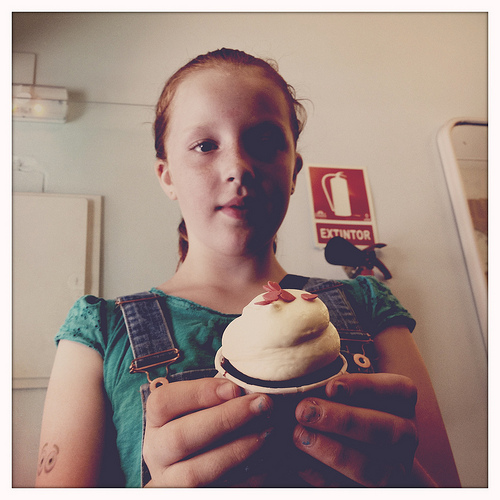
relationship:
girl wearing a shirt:
[1, 47, 463, 479] [89, 269, 456, 387]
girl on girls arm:
[1, 47, 463, 479] [33, 337, 103, 487]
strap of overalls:
[113, 291, 185, 378] [111, 272, 392, 491]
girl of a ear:
[1, 47, 463, 479] [146, 146, 181, 198]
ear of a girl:
[289, 148, 306, 195] [1, 47, 463, 479]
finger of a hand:
[143, 377, 238, 423] [143, 375, 272, 486]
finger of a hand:
[135, 391, 269, 456] [143, 375, 272, 486]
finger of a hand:
[151, 425, 277, 483] [143, 375, 272, 486]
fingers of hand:
[282, 373, 425, 483] [292, 346, 452, 483]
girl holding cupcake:
[1, 47, 463, 479] [212, 275, 351, 428]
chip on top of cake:
[300, 289, 317, 300] [219, 278, 341, 389]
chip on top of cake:
[278, 287, 296, 303] [219, 278, 341, 389]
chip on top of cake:
[256, 292, 277, 306] [219, 278, 341, 389]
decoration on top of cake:
[262, 291, 279, 302] [219, 278, 341, 389]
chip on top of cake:
[262, 279, 281, 291] [219, 278, 341, 389]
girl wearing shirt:
[1, 47, 463, 479] [55, 273, 450, 491]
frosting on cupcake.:
[215, 280, 342, 375] [159, 273, 397, 393]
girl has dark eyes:
[95, 38, 426, 458] [193, 137, 320, 165]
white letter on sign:
[361, 223, 375, 243] [300, 153, 381, 254]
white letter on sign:
[341, 225, 355, 245] [300, 153, 381, 254]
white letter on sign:
[314, 223, 331, 244] [300, 153, 381, 254]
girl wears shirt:
[1, 47, 463, 479] [56, 275, 416, 490]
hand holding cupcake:
[136, 375, 289, 487] [214, 277, 356, 449]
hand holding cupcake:
[297, 367, 426, 484] [214, 277, 356, 449]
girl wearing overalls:
[1, 47, 463, 479] [310, 275, 366, 377]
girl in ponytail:
[1, 47, 463, 479] [169, 218, 213, 280]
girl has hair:
[1, 47, 463, 479] [139, 32, 305, 272]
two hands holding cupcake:
[146, 384, 420, 486] [221, 287, 346, 386]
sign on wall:
[297, 161, 390, 249] [15, 13, 493, 499]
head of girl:
[157, 46, 294, 273] [1, 47, 463, 479]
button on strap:
[348, 347, 376, 374] [293, 270, 379, 350]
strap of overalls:
[293, 270, 379, 350] [111, 272, 392, 491]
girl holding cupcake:
[1, 47, 463, 479] [188, 286, 366, 419]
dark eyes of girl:
[187, 137, 280, 154] [1, 47, 463, 479]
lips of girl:
[215, 192, 267, 223] [1, 47, 463, 479]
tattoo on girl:
[30, 432, 66, 479] [1, 47, 463, 479]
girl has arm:
[1, 47, 463, 479] [25, 331, 104, 475]